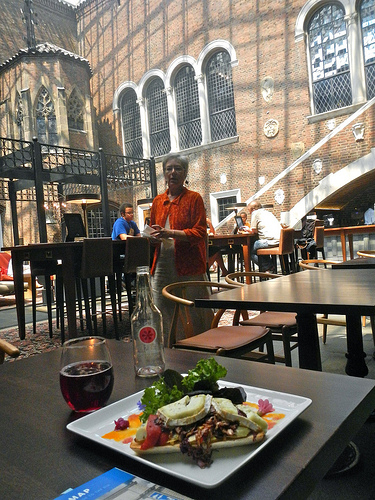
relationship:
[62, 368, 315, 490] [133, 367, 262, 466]
plate with sandwich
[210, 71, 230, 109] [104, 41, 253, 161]
mesh over windows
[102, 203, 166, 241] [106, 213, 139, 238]
man wears shirt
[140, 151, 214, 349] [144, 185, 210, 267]
person wears shirt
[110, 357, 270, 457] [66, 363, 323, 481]
sandwich on plate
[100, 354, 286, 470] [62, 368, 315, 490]
food on plate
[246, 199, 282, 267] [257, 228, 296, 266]
man on chair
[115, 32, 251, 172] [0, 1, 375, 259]
windows on building